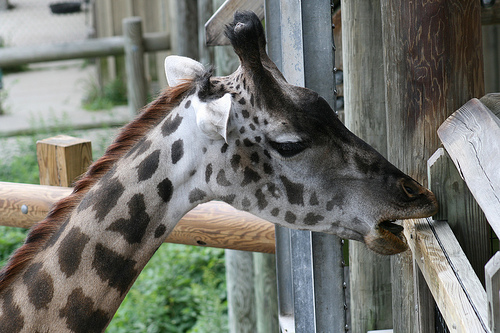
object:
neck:
[0, 101, 201, 333]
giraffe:
[0, 10, 436, 333]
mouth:
[373, 203, 441, 253]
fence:
[402, 93, 500, 333]